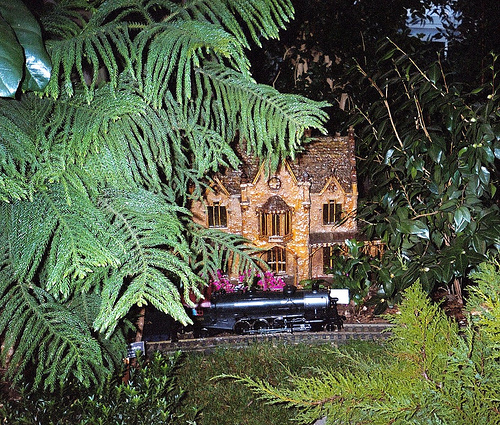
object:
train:
[166, 279, 343, 341]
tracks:
[121, 323, 391, 354]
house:
[184, 132, 386, 289]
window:
[321, 198, 347, 226]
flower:
[273, 277, 285, 292]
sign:
[123, 341, 146, 361]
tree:
[3, 3, 332, 391]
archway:
[257, 245, 299, 293]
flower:
[221, 282, 235, 292]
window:
[257, 197, 295, 243]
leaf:
[451, 207, 468, 227]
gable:
[318, 175, 345, 196]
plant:
[331, 113, 496, 315]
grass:
[161, 338, 391, 422]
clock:
[266, 178, 281, 191]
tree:
[273, 0, 430, 126]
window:
[206, 201, 231, 228]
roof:
[186, 135, 360, 195]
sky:
[401, 2, 474, 55]